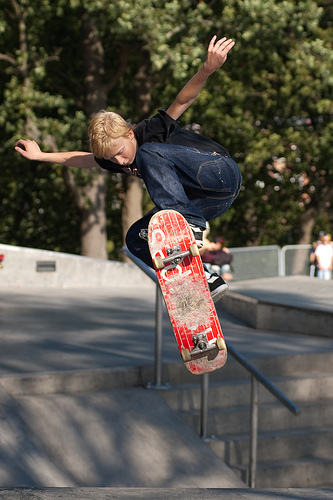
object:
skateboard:
[147, 208, 228, 376]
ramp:
[1, 383, 255, 487]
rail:
[121, 244, 300, 495]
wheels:
[216, 337, 226, 351]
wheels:
[181, 348, 192, 361]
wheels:
[189, 244, 199, 257]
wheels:
[154, 256, 165, 270]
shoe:
[207, 272, 230, 304]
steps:
[153, 353, 333, 487]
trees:
[1, 0, 333, 263]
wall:
[2, 242, 159, 294]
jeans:
[124, 141, 243, 275]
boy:
[14, 34, 243, 305]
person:
[307, 231, 333, 279]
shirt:
[314, 241, 332, 270]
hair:
[89, 108, 132, 161]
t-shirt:
[93, 108, 230, 180]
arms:
[149, 33, 235, 133]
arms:
[13, 138, 122, 169]